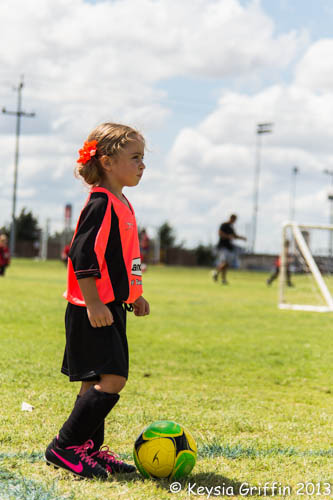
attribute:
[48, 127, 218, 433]
girl — little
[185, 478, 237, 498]
keysia — white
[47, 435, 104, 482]
soccer cleat — pink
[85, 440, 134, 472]
soccer cleat — pink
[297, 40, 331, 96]
cloud — white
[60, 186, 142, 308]
soccer jersey — orange, black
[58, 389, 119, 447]
shin guards — black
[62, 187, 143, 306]
shirt — orange, black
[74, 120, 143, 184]
hair — blonde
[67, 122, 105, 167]
flower — orange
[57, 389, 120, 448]
socks — black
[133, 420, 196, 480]
soccer ball — green, yellow, black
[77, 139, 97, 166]
flower — orange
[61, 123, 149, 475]
girl — little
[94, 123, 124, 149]
hair — girl's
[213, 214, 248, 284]
male — adult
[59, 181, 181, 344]
jersey — orange, black, soccer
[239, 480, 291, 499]
griffin — white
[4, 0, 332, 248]
sky — cloudy, blue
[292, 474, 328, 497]
number — white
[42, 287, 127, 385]
shorts — black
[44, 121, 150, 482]
girl — little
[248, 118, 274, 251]
stadium light — night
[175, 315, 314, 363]
grass field — green, soccer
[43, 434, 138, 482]
cleats — pink, black, soccer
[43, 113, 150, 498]
player — soccer